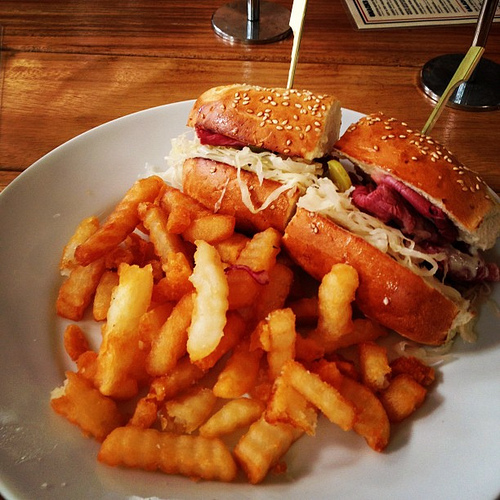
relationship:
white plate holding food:
[2, 164, 56, 487] [312, 262, 359, 338]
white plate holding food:
[2, 164, 56, 487] [189, 84, 311, 221]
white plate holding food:
[2, 164, 56, 487] [311, 121, 498, 348]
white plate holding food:
[2, 164, 56, 487] [102, 426, 232, 480]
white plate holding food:
[2, 164, 56, 487] [185, 241, 229, 359]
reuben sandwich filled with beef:
[168, 77, 492, 344] [351, 174, 498, 282]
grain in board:
[11, 6, 483, 136] [1, 0, 498, 65]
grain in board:
[11, 6, 483, 136] [0, 47, 498, 188]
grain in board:
[11, 6, 483, 136] [0, 172, 20, 191]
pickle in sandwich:
[318, 153, 355, 199] [182, 80, 499, 347]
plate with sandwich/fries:
[4, 80, 496, 497] [41, 78, 498, 478]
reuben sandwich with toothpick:
[168, 77, 492, 344] [434, 47, 475, 142]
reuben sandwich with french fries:
[168, 77, 492, 344] [55, 174, 435, 477]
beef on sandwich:
[351, 174, 498, 282] [182, 80, 499, 347]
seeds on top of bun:
[218, 84, 331, 143] [178, 79, 341, 234]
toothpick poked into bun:
[280, 8, 329, 108] [214, 71, 344, 136]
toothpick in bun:
[420, 45, 485, 135] [333, 110, 499, 250]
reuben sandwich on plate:
[168, 77, 493, 337] [4, 80, 496, 497]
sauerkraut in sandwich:
[167, 127, 315, 192] [182, 80, 499, 347]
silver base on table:
[209, 2, 300, 47] [2, 2, 499, 198]